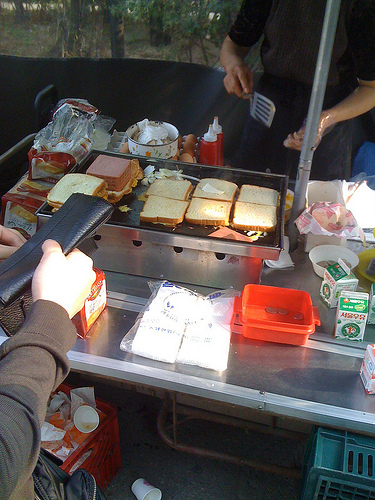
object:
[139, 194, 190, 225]
sandwiches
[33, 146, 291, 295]
grill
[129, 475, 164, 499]
cup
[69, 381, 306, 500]
ground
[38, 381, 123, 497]
crate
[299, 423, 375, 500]
crate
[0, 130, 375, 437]
table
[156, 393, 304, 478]
bar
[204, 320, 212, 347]
napkins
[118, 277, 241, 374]
package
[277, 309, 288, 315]
quarters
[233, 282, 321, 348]
box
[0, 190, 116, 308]
wallet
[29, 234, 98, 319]
hands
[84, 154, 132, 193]
meat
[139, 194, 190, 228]
bread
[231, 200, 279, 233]
bread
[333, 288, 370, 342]
carton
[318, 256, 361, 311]
carton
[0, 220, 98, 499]
person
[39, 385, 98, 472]
rubbish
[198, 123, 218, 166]
bottles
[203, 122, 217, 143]
tops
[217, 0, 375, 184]
person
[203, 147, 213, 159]
ketchup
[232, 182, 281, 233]
sandwich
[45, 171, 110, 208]
sandwich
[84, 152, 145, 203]
stack